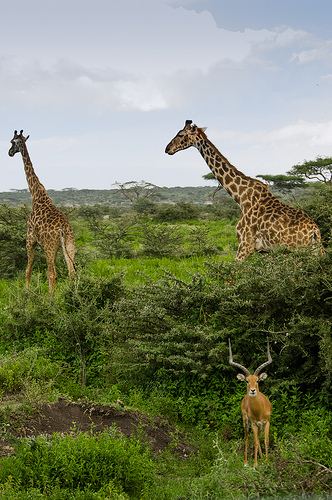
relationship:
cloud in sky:
[0, 0, 332, 189] [10, 13, 325, 102]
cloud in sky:
[0, 0, 332, 189] [1, 1, 331, 115]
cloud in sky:
[62, 73, 166, 122] [27, 28, 329, 125]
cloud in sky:
[0, 0, 332, 189] [0, 0, 327, 180]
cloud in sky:
[0, 0, 332, 189] [30, 20, 325, 113]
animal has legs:
[162, 119, 325, 285] [246, 426, 265, 451]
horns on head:
[187, 123, 206, 134] [233, 368, 266, 400]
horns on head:
[10, 125, 33, 145] [233, 368, 266, 400]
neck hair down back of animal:
[185, 119, 269, 187] [162, 119, 325, 285]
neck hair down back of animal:
[23, 138, 48, 194] [8, 129, 77, 292]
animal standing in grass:
[8, 129, 77, 292] [4, 211, 309, 288]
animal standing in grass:
[162, 119, 325, 285] [4, 211, 309, 288]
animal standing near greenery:
[162, 119, 323, 259] [118, 257, 325, 338]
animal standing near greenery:
[6, 126, 83, 295] [82, 201, 213, 258]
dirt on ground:
[16, 406, 180, 452] [5, 368, 325, 499]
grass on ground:
[156, 451, 216, 477] [0, 220, 331, 497]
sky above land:
[52, 17, 226, 126] [38, 284, 152, 492]